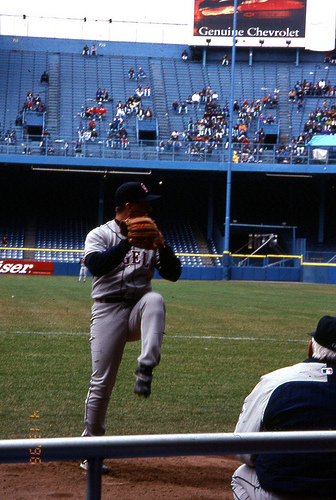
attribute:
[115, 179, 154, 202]
hat — blue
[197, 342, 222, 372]
grass — green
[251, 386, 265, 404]
jacket — white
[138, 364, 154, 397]
sneakers — black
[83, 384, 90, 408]
stripe — blue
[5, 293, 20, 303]
ball — small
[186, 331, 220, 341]
line — thin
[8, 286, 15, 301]
ball — white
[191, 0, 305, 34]
screen — big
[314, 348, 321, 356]
hair — white, tip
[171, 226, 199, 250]
chairs — empty, blue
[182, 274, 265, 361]
field — baseball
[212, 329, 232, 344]
line — white, on the ground 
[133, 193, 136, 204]
pitcher — winding up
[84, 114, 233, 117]
people — in background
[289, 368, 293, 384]
man — old, with a cap, kneeling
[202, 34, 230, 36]
billboard — on top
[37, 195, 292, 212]
stadium — top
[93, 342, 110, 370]
player — baseball, poised, throw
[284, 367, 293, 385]
man — crouched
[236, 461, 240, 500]
knees — his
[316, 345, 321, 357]
hair — white, straggly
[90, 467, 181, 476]
mound — dirt, baseball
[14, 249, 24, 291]
part — advertisement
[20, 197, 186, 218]
stands — baseball, empty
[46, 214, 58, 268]
level — first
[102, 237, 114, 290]
player — baseball , in the distance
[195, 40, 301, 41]
lights — flood , four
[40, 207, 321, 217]
stadium — baseball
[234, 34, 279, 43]
advertisement — Chevrolet, billboard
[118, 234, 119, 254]
pitcher — baseball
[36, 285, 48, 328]
field — baseball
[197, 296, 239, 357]
field — baseball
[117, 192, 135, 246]
pitcher — baseball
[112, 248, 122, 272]
pitcher — baseball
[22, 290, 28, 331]
field — baseball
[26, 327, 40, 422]
field — baseball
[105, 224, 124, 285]
pitcher — baseball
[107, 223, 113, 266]
pitcher — baseball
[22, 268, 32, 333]
field — baseball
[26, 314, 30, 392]
field — baseball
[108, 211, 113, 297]
pitcher — baseball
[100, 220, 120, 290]
pitcher — baseball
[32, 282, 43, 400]
field — baseball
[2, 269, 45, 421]
field — baseball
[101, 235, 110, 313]
pitcher — baseball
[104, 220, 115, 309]
pitcher — baseball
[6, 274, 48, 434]
field — baseball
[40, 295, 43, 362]
field — baseball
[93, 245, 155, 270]
pitcher — baseball